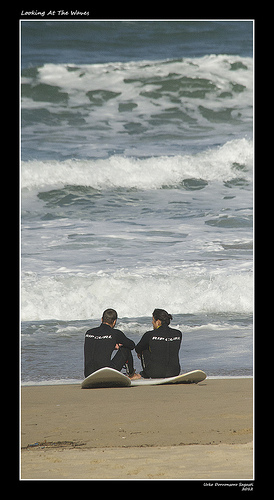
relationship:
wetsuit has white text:
[138, 326, 183, 378] [154, 332, 183, 344]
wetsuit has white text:
[82, 323, 136, 381] [84, 332, 116, 343]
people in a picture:
[81, 309, 185, 381] [18, 19, 254, 480]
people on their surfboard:
[81, 309, 185, 381] [81, 367, 132, 388]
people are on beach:
[81, 309, 185, 381] [19, 384, 261, 485]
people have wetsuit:
[81, 309, 185, 381] [136, 326, 183, 378]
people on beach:
[81, 309, 185, 381] [19, 384, 261, 485]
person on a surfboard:
[84, 306, 137, 383] [81, 367, 132, 391]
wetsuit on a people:
[138, 326, 183, 378] [135, 307, 182, 378]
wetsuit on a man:
[82, 323, 136, 381] [84, 306, 137, 383]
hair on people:
[154, 306, 169, 327] [135, 307, 182, 378]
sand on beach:
[37, 423, 112, 443] [19, 384, 261, 485]